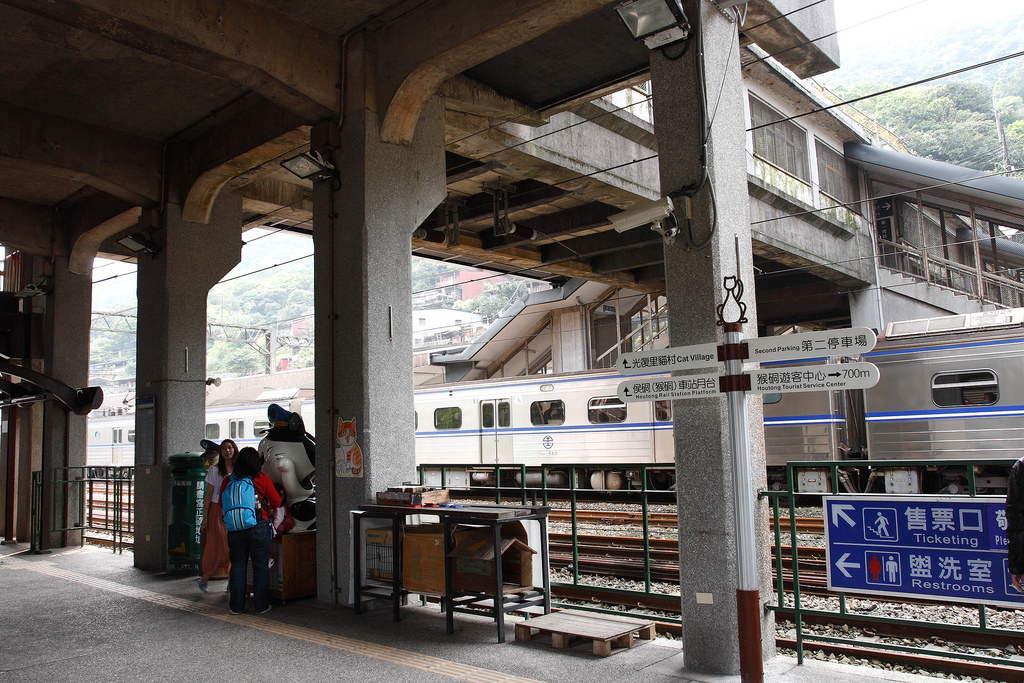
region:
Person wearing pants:
[213, 514, 278, 610]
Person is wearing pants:
[217, 498, 288, 617]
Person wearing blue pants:
[217, 513, 281, 611]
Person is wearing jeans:
[223, 510, 282, 615]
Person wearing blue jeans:
[217, 510, 279, 618]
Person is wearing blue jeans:
[220, 513, 278, 612]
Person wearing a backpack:
[216, 462, 270, 538]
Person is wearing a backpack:
[213, 459, 264, 546]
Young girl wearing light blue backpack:
[209, 440, 285, 624]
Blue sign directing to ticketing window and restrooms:
[822, 493, 1022, 604]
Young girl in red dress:
[187, 437, 244, 589]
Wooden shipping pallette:
[513, 598, 659, 659]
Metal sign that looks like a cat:
[705, 262, 753, 336]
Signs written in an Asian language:
[612, 320, 881, 406]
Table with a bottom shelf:
[346, 480, 558, 646]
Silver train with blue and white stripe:
[86, 301, 1020, 501]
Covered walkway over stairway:
[844, 139, 1022, 232]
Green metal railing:
[411, 455, 1012, 656]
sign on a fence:
[808, 468, 1019, 624]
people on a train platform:
[190, 390, 317, 631]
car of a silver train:
[415, 366, 670, 498]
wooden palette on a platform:
[512, 585, 659, 668]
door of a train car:
[466, 394, 526, 474]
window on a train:
[921, 360, 1004, 418]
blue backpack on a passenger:
[213, 472, 270, 537]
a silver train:
[76, 316, 1010, 475]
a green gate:
[422, 461, 1015, 652]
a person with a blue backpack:
[223, 452, 271, 596]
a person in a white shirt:
[202, 436, 241, 573]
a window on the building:
[748, 97, 810, 178]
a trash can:
[400, 512, 496, 631]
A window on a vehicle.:
[423, 403, 465, 430]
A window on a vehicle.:
[482, 402, 498, 428]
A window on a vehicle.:
[498, 396, 512, 425]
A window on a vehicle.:
[521, 403, 563, 429]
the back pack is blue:
[205, 468, 272, 544]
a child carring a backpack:
[212, 440, 298, 619]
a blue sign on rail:
[822, 483, 1015, 624]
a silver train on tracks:
[130, 281, 991, 513]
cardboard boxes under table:
[356, 521, 534, 597]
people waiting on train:
[168, 401, 318, 621]